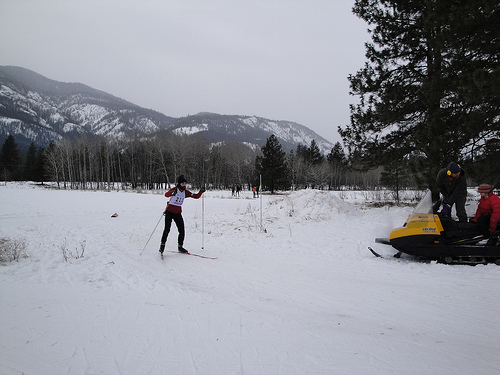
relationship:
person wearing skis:
[156, 175, 205, 258] [170, 246, 218, 260]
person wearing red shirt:
[156, 175, 205, 258] [164, 187, 201, 214]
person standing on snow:
[156, 175, 205, 258] [0, 180, 499, 374]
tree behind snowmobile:
[335, 4, 499, 208] [366, 192, 499, 264]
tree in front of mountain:
[252, 132, 296, 193] [0, 67, 338, 158]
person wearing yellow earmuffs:
[432, 160, 468, 221] [447, 160, 462, 175]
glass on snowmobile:
[405, 187, 439, 222] [366, 192, 499, 264]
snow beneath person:
[0, 180, 499, 374] [156, 175, 205, 258]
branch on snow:
[59, 243, 88, 259] [0, 180, 499, 374]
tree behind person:
[335, 4, 499, 208] [432, 160, 468, 221]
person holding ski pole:
[156, 175, 205, 258] [199, 193, 207, 259]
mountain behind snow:
[0, 67, 338, 158] [0, 180, 499, 374]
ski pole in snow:
[199, 193, 207, 259] [0, 180, 499, 374]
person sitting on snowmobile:
[453, 182, 499, 247] [366, 192, 499, 264]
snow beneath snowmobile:
[0, 180, 499, 374] [366, 192, 499, 264]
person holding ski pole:
[156, 175, 205, 258] [137, 192, 174, 257]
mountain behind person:
[0, 67, 338, 158] [156, 175, 205, 258]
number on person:
[172, 196, 185, 203] [156, 175, 205, 258]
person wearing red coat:
[453, 182, 499, 247] [470, 193, 499, 234]